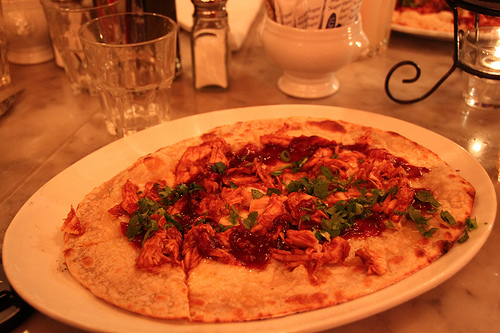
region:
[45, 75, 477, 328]
This is a flatbread.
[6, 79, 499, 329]
This is a white plate.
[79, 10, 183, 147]
This is a glass.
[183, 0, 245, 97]
This is a salt shaker.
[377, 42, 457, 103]
This is a wire.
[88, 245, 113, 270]
This is the color tan.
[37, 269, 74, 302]
This is the color white.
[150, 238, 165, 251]
This is the color red.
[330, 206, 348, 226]
This is the color green.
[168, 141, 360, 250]
These are toppings.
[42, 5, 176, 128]
There are 2 glasses on the table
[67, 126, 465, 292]
The plate is white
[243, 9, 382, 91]
There is sugar in the bowl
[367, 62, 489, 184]
The table is grey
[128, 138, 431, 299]
The main food is bread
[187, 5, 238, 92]
There is salt on the table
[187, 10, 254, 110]
The salt is white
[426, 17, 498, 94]
There is a candle on the table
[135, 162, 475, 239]
There are vegetables on the plate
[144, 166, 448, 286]
The vegetables are green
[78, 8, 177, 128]
a clear drinking glass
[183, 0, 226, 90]
a glass salt shaker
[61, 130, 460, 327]
a small cut pizza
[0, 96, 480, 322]
a white pizza plate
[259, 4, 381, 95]
a white cup of things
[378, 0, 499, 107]
a black metal candle holder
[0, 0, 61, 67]
a small white cup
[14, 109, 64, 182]
a small patch of table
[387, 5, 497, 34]
a small plate of food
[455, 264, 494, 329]
a small patch of table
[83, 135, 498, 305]
the plate is white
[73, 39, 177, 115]
the glass is clear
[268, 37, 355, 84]
the cup is white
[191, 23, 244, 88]
the slat shaker is made of glass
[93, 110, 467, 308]
the pizza looks yummy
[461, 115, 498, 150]
light reflection on the table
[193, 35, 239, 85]
the salt is white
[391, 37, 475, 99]
the frame is mettalic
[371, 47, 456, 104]
the metallic is black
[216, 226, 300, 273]
the sauce is red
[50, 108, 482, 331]
Pizza on plate on table.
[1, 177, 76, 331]
Edge of white pizza plate.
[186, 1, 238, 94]
Salt shaker sitting on table.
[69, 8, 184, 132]
Empty glass sitting on table.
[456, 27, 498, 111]
Candle in glass holder sitting on table.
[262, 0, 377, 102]
Packets of sugar in white holder sitting on table.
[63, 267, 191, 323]
Crust of baked pizza.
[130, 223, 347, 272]
Shredded meat on top of pizza.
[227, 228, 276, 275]
Red tomato sauce on top of pizza.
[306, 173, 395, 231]
Fresh green herb on top of pizza.